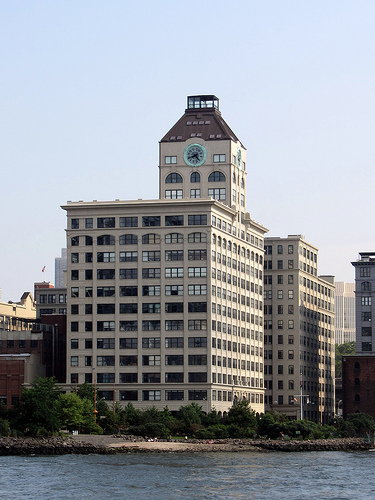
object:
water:
[75, 451, 340, 482]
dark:
[40, 430, 310, 492]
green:
[8, 375, 81, 435]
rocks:
[15, 423, 359, 460]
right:
[296, 286, 370, 453]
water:
[13, 479, 366, 500]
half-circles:
[165, 172, 185, 186]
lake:
[1, 416, 375, 498]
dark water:
[1, 455, 373, 498]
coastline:
[1, 432, 374, 450]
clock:
[183, 143, 208, 167]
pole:
[295, 386, 309, 420]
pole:
[92, 366, 97, 431]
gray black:
[188, 146, 202, 164]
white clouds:
[249, 29, 369, 215]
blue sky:
[3, 4, 161, 133]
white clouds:
[1, 119, 154, 194]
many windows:
[68, 229, 263, 404]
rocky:
[3, 437, 373, 453]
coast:
[3, 411, 371, 497]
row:
[68, 265, 210, 283]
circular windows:
[162, 169, 228, 181]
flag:
[40, 262, 47, 274]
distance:
[31, 260, 56, 283]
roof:
[61, 198, 233, 216]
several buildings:
[1, 90, 374, 424]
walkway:
[63, 433, 258, 452]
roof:
[263, 234, 320, 250]